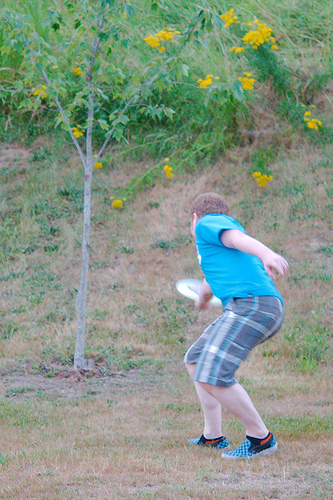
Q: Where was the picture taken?
A: It was taken at the field.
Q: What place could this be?
A: It is a field.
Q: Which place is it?
A: It is a field.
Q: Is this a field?
A: Yes, it is a field.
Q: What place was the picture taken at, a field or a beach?
A: It was taken at a field.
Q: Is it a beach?
A: No, it is a field.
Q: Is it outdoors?
A: Yes, it is outdoors.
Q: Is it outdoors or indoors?
A: It is outdoors.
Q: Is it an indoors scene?
A: No, it is outdoors.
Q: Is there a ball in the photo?
A: No, there are no balls.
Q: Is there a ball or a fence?
A: No, there are no balls or fences.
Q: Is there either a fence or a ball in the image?
A: No, there are no balls or fences.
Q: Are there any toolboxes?
A: No, there are no toolboxes.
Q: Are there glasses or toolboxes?
A: No, there are no toolboxes or glasses.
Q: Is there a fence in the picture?
A: No, there are no fences.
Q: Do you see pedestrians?
A: No, there are no pedestrians.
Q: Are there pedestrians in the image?
A: No, there are no pedestrians.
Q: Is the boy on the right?
A: Yes, the boy is on the right of the image.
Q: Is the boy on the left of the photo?
A: No, the boy is on the right of the image.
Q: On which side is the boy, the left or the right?
A: The boy is on the right of the image.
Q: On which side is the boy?
A: The boy is on the right of the image.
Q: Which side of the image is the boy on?
A: The boy is on the right of the image.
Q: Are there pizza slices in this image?
A: No, there are no pizza slices.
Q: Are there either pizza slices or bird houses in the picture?
A: No, there are no pizza slices or bird houses.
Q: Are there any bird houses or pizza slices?
A: No, there are no pizza slices or bird houses.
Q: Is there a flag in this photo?
A: No, there are no flags.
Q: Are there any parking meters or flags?
A: No, there are no flags or parking meters.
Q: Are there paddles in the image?
A: No, there are no paddles.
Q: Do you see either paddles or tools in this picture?
A: No, there are no paddles or tools.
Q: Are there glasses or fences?
A: No, there are no glasses or fences.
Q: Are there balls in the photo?
A: No, there are no balls.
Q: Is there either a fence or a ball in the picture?
A: No, there are no balls or fences.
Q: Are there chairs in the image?
A: No, there are no chairs.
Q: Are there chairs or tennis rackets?
A: No, there are no chairs or tennis rackets.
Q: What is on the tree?
A: The flower is on the tree.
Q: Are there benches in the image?
A: No, there are no benches.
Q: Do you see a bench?
A: No, there are no benches.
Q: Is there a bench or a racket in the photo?
A: No, there are no benches or rackets.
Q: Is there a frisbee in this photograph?
A: Yes, there is a frisbee.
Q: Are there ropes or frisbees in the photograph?
A: Yes, there is a frisbee.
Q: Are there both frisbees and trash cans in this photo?
A: No, there is a frisbee but no trash cans.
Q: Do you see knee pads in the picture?
A: No, there are no knee pads.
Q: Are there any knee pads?
A: No, there are no knee pads.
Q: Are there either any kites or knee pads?
A: No, there are no knee pads or kites.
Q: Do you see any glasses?
A: No, there are no glasses.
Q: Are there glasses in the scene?
A: No, there are no glasses.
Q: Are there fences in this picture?
A: No, there are no fences.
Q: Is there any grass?
A: Yes, there is grass.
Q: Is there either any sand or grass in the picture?
A: Yes, there is grass.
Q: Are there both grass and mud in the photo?
A: No, there is grass but no mud.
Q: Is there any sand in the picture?
A: No, there is no sand.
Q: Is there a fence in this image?
A: No, there are no fences.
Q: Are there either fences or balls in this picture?
A: No, there are no fences or balls.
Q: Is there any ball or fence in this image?
A: No, there are no fences or balls.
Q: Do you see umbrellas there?
A: No, there are no umbrellas.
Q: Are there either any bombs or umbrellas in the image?
A: No, there are no umbrellas or bombs.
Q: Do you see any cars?
A: No, there are no cars.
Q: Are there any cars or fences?
A: No, there are no cars or fences.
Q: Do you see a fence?
A: No, there are no fences.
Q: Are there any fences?
A: No, there are no fences.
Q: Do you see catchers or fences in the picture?
A: No, there are no fences or catchers.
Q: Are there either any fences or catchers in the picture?
A: No, there are no fences or catchers.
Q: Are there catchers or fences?
A: No, there are no fences or catchers.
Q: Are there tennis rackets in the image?
A: No, there are no tennis rackets.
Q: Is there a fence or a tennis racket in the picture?
A: No, there are no rackets or fences.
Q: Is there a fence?
A: No, there are no fences.